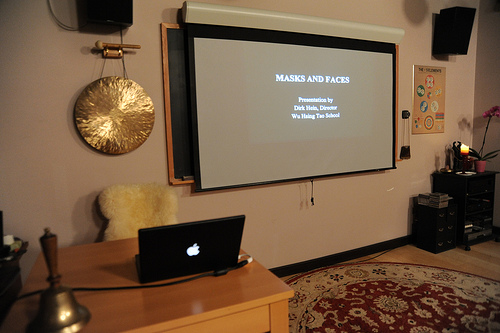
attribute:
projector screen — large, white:
[192, 36, 394, 182]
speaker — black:
[69, 2, 144, 36]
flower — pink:
[468, 97, 496, 117]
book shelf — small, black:
[432, 167, 499, 246]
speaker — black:
[431, 4, 477, 55]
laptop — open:
[131, 208, 248, 288]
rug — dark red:
[272, 261, 492, 329]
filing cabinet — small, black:
[408, 198, 464, 255]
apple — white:
[178, 236, 201, 258]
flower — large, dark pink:
[480, 100, 498, 123]